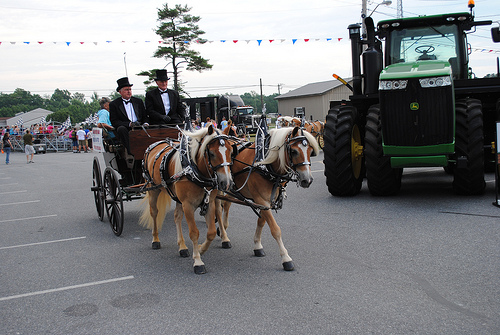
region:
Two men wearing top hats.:
[113, 64, 183, 128]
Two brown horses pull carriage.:
[144, 122, 313, 281]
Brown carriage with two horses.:
[89, 127, 319, 276]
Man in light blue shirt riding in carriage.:
[92, 94, 112, 133]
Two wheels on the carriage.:
[87, 155, 133, 236]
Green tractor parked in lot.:
[320, 10, 497, 200]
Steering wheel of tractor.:
[415, 44, 437, 55]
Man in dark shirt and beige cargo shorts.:
[21, 128, 37, 163]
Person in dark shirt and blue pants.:
[0, 128, 15, 167]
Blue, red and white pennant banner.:
[1, 35, 495, 54]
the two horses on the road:
[132, 129, 325, 278]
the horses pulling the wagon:
[86, 69, 313, 286]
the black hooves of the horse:
[147, 235, 302, 277]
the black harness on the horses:
[143, 135, 205, 204]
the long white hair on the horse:
[177, 121, 219, 155]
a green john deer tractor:
[320, 10, 494, 209]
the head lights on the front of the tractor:
[379, 69, 454, 94]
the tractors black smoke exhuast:
[362, 10, 373, 52]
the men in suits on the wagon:
[108, 61, 184, 151]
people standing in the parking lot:
[0, 126, 38, 168]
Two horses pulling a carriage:
[88, 65, 321, 279]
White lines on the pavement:
[1, 169, 138, 302]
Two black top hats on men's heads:
[113, 64, 177, 98]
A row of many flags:
[0, 35, 499, 55]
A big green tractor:
[321, 4, 498, 204]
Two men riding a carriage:
[89, 63, 191, 240]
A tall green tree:
[136, 3, 214, 99]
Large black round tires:
[319, 92, 493, 204]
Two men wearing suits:
[105, 62, 189, 131]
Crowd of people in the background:
[1, 116, 99, 169]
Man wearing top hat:
[142, 69, 188, 122]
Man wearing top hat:
[104, 76, 150, 126]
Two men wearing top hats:
[112, 68, 185, 126]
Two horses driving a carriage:
[88, 65, 318, 280]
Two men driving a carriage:
[93, 67, 305, 280]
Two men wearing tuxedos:
[99, 62, 186, 131]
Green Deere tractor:
[319, 9, 496, 190]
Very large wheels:
[316, 90, 398, 201]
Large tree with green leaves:
[143, 0, 213, 100]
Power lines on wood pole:
[220, 69, 295, 113]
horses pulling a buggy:
[141, 103, 313, 276]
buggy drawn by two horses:
[77, 110, 196, 242]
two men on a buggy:
[107, 58, 187, 156]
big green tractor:
[316, 3, 499, 194]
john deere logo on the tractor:
[406, 100, 423, 114]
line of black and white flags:
[13, 113, 99, 137]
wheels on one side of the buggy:
[85, 152, 133, 235]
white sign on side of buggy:
[86, 124, 109, 155]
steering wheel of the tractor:
[411, 40, 443, 60]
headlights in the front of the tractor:
[376, 75, 453, 100]